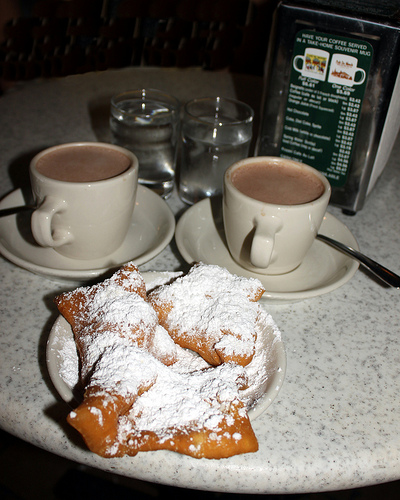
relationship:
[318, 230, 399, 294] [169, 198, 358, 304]
spoon on saucer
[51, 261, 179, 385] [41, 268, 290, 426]
pastry on top of plate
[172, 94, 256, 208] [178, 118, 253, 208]
glass holding water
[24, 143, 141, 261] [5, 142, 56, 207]
cup casting shadow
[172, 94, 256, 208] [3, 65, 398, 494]
glass on top of table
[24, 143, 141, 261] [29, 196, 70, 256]
cup has handle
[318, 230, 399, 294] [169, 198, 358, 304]
spoon on top of saucer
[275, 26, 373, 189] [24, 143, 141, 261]
menu near cup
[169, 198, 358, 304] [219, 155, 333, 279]
saucer beneath cup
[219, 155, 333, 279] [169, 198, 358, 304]
cup on top of saucer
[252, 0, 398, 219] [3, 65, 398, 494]
napkin dispenser sits on table